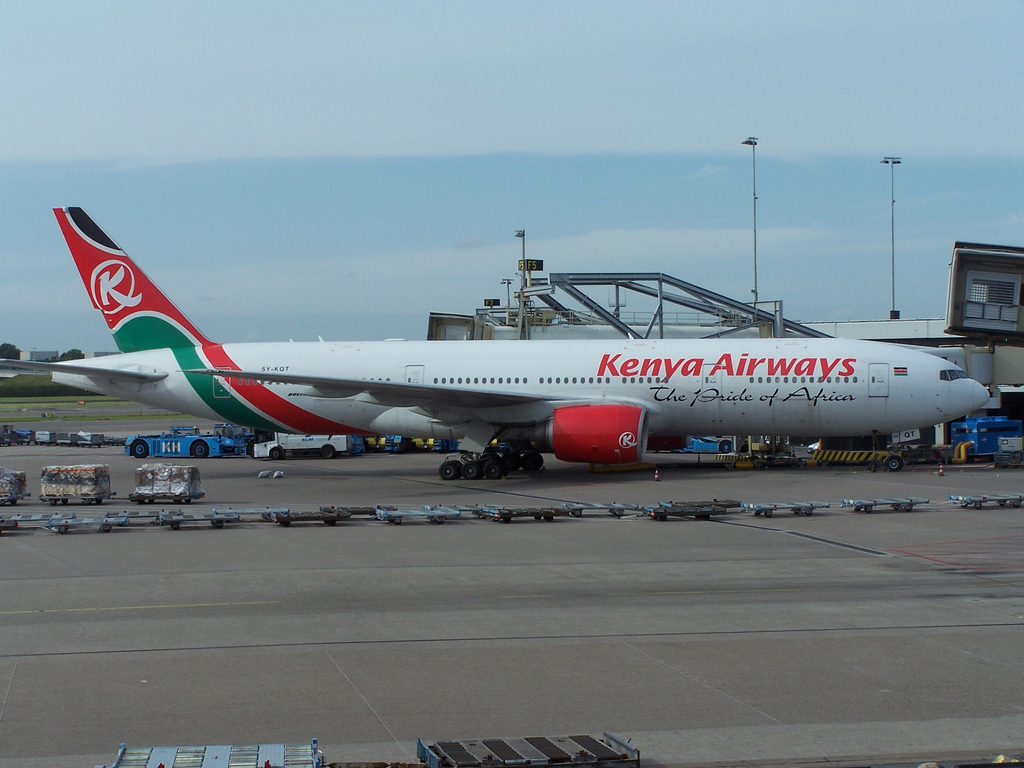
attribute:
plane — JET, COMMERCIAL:
[25, 183, 1008, 486]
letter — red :
[617, 348, 646, 387]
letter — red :
[638, 354, 667, 385]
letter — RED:
[659, 348, 683, 387]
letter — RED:
[681, 350, 705, 379]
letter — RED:
[701, 344, 738, 381]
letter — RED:
[759, 350, 794, 379]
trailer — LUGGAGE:
[405, 724, 639, 751]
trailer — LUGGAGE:
[746, 487, 835, 520]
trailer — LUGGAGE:
[945, 493, 993, 517]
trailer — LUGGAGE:
[647, 491, 743, 522]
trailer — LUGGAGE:
[564, 491, 636, 518]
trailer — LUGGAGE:
[484, 497, 562, 524]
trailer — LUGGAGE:
[372, 497, 463, 532]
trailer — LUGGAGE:
[268, 502, 348, 526]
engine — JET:
[532, 396, 660, 468]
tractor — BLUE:
[121, 418, 243, 466]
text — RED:
[584, 342, 866, 381]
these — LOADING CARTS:
[11, 402, 465, 536]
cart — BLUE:
[119, 424, 243, 472]